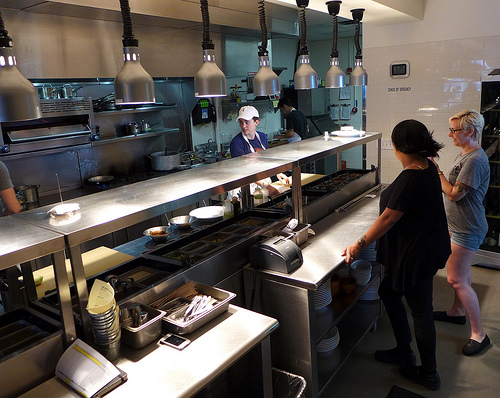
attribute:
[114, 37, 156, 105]
light — hanging, metal, warming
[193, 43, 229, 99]
light — hanging, metal, warming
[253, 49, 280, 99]
light — hanging, metal, warming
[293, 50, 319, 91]
light — hanging, metal, warming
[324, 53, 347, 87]
light — hanging, metal, warming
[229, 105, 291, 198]
woman — serving, cooking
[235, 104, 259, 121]
cap — white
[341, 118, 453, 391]
woman — ordering, watching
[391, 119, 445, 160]
hair — black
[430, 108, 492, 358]
woman — blonde, ordering, watching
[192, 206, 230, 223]
dish — white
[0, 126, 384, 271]
shelf — steel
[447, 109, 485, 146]
hair — blonde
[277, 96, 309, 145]
cook — preparing, cooking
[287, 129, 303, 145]
apron — white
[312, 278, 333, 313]
plates — clean, stacked, white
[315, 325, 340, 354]
plates — clean, stacked, white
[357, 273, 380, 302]
plates — clean, stacked, white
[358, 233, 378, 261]
plates — clean, stacked, white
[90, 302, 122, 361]
cups — stacked, stainless steel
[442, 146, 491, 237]
shirt — grey